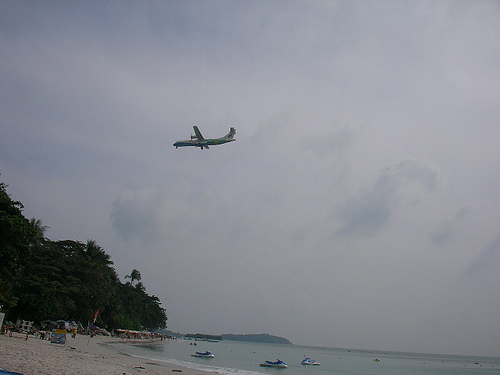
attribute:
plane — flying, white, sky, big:
[171, 119, 255, 159]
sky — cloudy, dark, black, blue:
[279, 53, 380, 138]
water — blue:
[232, 339, 285, 364]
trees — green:
[46, 255, 118, 298]